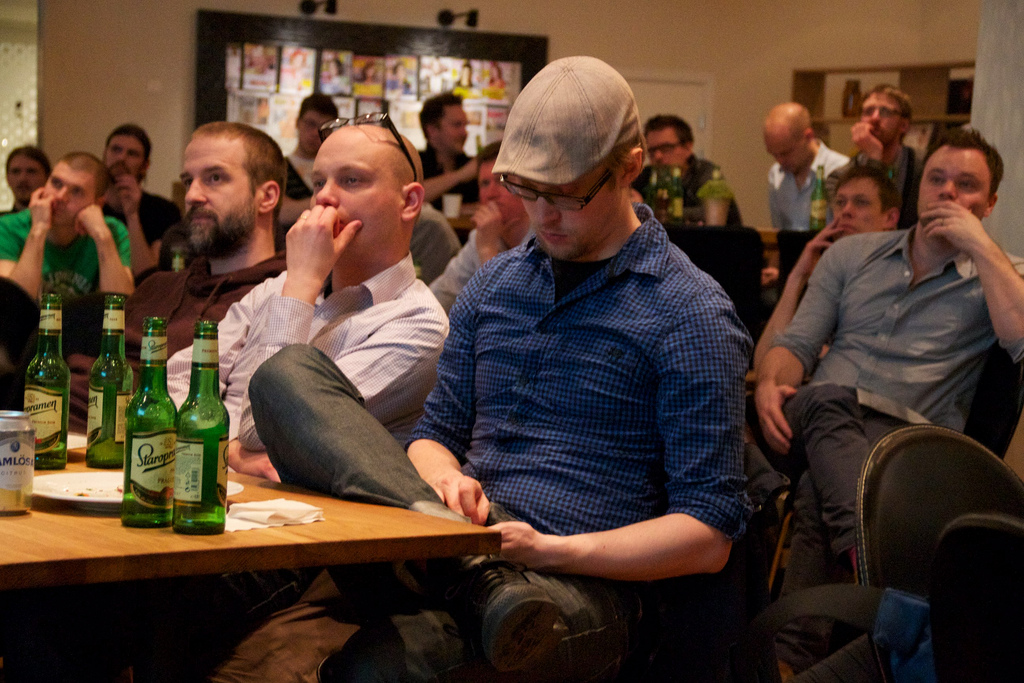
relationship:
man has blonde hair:
[64, 121, 286, 435] [182, 119, 285, 193]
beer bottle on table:
[172, 320, 230, 534] [5, 376, 505, 553]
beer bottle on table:
[116, 304, 178, 524] [0, 362, 538, 610]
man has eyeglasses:
[217, 56, 754, 682] [455, 158, 655, 225]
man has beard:
[155, 125, 277, 280] [155, 185, 267, 258]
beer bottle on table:
[172, 320, 230, 534] [22, 358, 558, 647]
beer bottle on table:
[182, 426, 224, 651] [11, 433, 501, 612]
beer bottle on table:
[172, 320, 230, 534] [36, 263, 390, 678]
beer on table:
[0, 410, 35, 513] [2, 430, 499, 596]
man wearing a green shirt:
[4, 150, 150, 302] [1, 201, 142, 310]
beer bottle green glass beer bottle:
[172, 320, 230, 534] [172, 320, 230, 534]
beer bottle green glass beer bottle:
[172, 320, 230, 534] [175, 279, 249, 532]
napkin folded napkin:
[224, 498, 326, 532] [227, 482, 329, 539]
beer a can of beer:
[0, 410, 35, 513] [0, 402, 77, 514]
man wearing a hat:
[414, 53, 756, 665] [495, 80, 626, 163]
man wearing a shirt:
[750, 137, 1022, 593] [782, 223, 992, 433]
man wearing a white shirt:
[149, 118, 454, 483] [316, 259, 449, 422]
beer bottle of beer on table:
[172, 320, 230, 534] [87, 521, 429, 683]